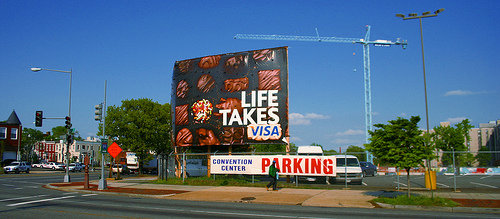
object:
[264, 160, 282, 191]
man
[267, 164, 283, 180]
jacket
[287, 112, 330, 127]
clouds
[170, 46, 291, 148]
billboard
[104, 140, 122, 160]
sign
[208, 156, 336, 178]
sign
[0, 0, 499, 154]
sky